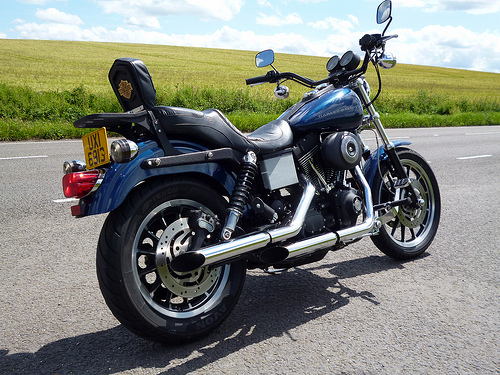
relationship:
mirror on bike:
[253, 49, 280, 68] [63, 1, 440, 346]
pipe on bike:
[172, 184, 318, 273] [63, 1, 440, 346]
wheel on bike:
[95, 178, 247, 348] [63, 1, 440, 346]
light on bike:
[62, 167, 105, 199] [63, 1, 440, 346]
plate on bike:
[82, 128, 115, 173] [63, 1, 440, 346]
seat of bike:
[109, 58, 292, 154] [63, 1, 440, 346]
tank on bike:
[275, 79, 367, 132] [63, 1, 440, 346]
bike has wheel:
[63, 1, 440, 346] [95, 178, 247, 348]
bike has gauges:
[63, 1, 440, 346] [325, 51, 361, 76]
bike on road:
[63, 1, 440, 346] [0, 125, 499, 374]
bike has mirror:
[63, 1, 440, 346] [253, 49, 280, 68]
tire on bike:
[367, 149, 444, 259] [63, 1, 440, 346]